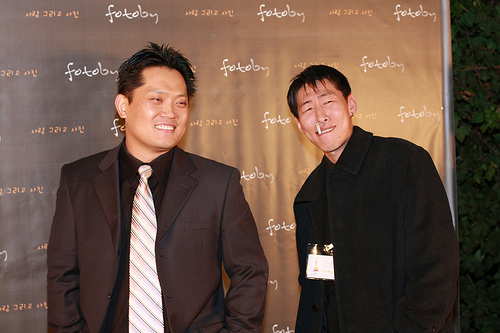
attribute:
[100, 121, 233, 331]
shirt — mans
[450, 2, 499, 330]
tree leaves — green 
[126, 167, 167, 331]
tie — mans, long, striped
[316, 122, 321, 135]
cigarette — white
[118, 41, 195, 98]
hair — mans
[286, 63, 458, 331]
man — mans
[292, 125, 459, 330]
coat — black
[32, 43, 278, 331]
man — black, collared, short, cut